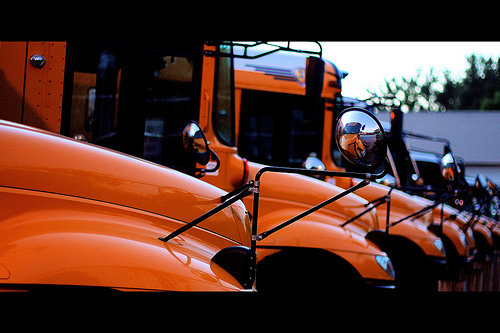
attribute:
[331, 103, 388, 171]
mirror — concave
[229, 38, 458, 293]
bus — dark, yellow, empty, school, orange, lined, orang, clean, parked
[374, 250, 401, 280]
light — reflecting, off, curved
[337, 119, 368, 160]
reflection — black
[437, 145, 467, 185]
frame — metal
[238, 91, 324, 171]
door — large, closed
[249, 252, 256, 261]
bolt — silver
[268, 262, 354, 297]
wheel — black